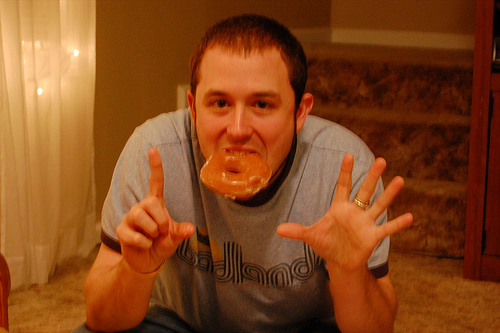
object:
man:
[81, 16, 413, 333]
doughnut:
[196, 146, 272, 202]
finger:
[145, 146, 163, 201]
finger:
[276, 217, 309, 240]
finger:
[332, 148, 355, 207]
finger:
[351, 155, 386, 213]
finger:
[365, 170, 403, 222]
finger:
[377, 209, 416, 237]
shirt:
[90, 101, 395, 330]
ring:
[352, 199, 369, 209]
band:
[121, 257, 167, 275]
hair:
[189, 12, 307, 112]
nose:
[226, 105, 253, 142]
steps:
[276, 40, 477, 258]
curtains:
[1, 1, 102, 289]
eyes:
[250, 99, 274, 113]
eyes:
[207, 95, 232, 113]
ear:
[294, 90, 314, 133]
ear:
[187, 90, 196, 123]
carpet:
[5, 245, 497, 332]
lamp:
[20, 30, 86, 100]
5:
[277, 152, 418, 266]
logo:
[172, 235, 329, 289]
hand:
[114, 146, 196, 263]